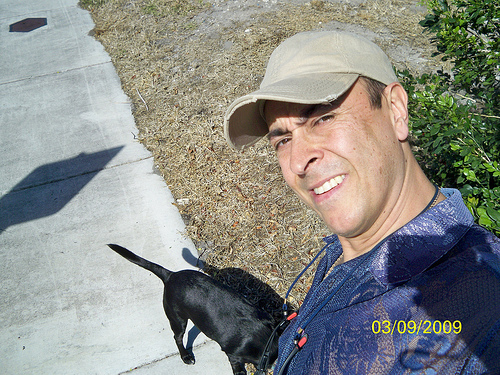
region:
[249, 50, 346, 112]
Man wearing tan hat.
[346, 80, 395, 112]
Man has dark hair.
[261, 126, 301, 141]
Man has dark eye brows.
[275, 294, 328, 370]
Sunglasses hanging from neck.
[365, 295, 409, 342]
Man wearing blue coat.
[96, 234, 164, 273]
Dog has black tail.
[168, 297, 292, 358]
Dog has black fur.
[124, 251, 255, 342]
Dog is standing on side walk.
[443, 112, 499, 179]
Green leaves on branches.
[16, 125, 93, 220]
Shadow of sign on sidewalk.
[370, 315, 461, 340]
date photo was taken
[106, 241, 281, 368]
small black dog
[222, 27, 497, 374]
man looking at camera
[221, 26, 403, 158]
man's tan ball cap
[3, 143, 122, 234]
shadow on sidewalk of sign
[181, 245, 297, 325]
shadow of dog on grass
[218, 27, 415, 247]
man frowning at camera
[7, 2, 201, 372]
sidewalk with shadow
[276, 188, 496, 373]
man's blue shirt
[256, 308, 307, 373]
glasses hanging from cord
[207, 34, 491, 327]
Man taking a selfie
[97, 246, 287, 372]
Black dog sniffing grass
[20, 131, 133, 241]
Shadow on the sidewalk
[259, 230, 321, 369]
Sunglasses hanging on his neck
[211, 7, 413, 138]
Man wearing baseball hat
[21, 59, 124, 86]
Crack in the sidewalk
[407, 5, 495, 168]
Bush behind mans head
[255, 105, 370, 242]
The man has sun in his eyes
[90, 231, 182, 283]
Dog has a straight tail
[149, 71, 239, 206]
The grass is brown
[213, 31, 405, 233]
a man wearing a hat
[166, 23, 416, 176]
a ma wearing a tan baseball cap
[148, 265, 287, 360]
a black dog on a sidewalk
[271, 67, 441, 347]
a man wearing a blue shirt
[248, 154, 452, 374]
a man wearing glasses around his neck on a string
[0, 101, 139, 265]
a shadow on a sidewalk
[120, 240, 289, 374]
a small black dog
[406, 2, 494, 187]
a green bush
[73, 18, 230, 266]
dead grass next to a sidewalk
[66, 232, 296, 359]
a black dog with a long tail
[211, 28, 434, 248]
man in tan baseball cap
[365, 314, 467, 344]
date stamp on photo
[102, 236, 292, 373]
small black dog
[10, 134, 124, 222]
shadow of sign on sidewalk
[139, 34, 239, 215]
dead brown grass next to sidewalk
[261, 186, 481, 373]
blue button down shirt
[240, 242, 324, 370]
eyeglasses hanging around neck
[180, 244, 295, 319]
shadow cast by dog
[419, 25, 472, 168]
green leaves on bushes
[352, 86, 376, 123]
freckles on man's face